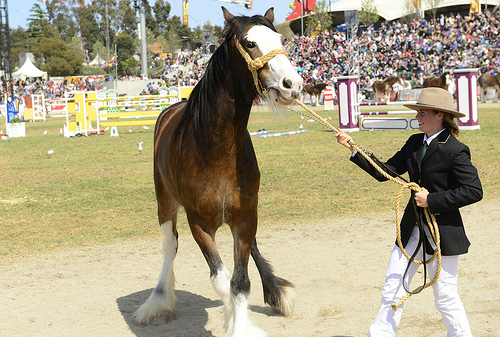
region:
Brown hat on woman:
[311, 63, 488, 295]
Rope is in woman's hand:
[239, 40, 487, 183]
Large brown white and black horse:
[156, 3, 366, 236]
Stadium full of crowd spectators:
[351, 6, 497, 174]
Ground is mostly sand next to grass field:
[27, 203, 383, 334]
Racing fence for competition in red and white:
[310, 56, 484, 178]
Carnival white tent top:
[2, 46, 97, 160]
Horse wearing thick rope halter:
[187, 8, 333, 203]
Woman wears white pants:
[319, 83, 497, 327]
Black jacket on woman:
[342, 80, 484, 227]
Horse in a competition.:
[117, 3, 332, 335]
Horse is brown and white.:
[128, 3, 321, 334]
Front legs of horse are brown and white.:
[191, 216, 258, 332]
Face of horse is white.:
[236, 15, 304, 105]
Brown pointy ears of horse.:
[215, 1, 283, 20]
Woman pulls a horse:
[125, 1, 488, 334]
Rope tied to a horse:
[283, 85, 450, 298]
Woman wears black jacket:
[335, 73, 492, 334]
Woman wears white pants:
[334, 76, 499, 334]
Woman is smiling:
[333, 82, 488, 334]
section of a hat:
[432, 90, 448, 100]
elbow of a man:
[476, 187, 483, 199]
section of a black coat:
[435, 160, 446, 180]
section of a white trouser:
[439, 272, 444, 312]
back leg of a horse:
[159, 200, 167, 297]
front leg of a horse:
[238, 220, 251, 272]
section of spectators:
[401, 28, 437, 60]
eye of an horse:
[245, 33, 252, 54]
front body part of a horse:
[203, 111, 232, 203]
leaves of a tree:
[58, 45, 66, 60]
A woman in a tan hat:
[334, 82, 488, 331]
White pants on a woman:
[371, 211, 486, 331]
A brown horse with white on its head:
[138, 6, 335, 330]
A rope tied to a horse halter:
[252, 83, 450, 308]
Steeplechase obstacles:
[60, 87, 217, 139]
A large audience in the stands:
[161, 7, 498, 100]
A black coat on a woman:
[337, 122, 483, 255]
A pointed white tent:
[10, 47, 57, 87]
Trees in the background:
[14, 0, 196, 80]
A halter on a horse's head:
[210, 4, 306, 109]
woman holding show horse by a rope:
[121, 6, 483, 335]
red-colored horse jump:
[333, 63, 483, 132]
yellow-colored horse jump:
[61, 83, 198, 135]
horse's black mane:
[174, 35, 239, 157]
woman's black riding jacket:
[351, 132, 483, 255]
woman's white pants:
[368, 226, 474, 335]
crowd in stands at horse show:
[168, 16, 499, 80]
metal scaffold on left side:
[0, 1, 19, 103]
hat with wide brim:
[403, 85, 469, 119]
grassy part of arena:
[1, 108, 498, 238]